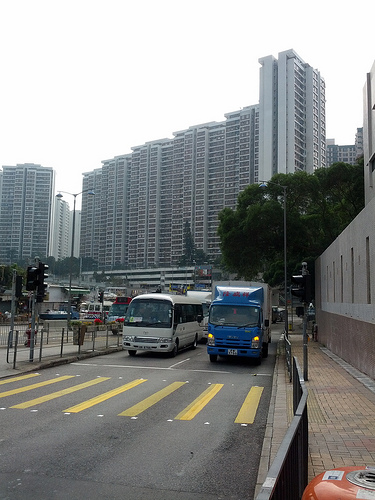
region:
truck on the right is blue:
[202, 274, 277, 365]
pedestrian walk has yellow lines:
[0, 367, 267, 433]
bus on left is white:
[118, 287, 204, 363]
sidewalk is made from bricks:
[263, 330, 373, 498]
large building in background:
[69, 52, 361, 294]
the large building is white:
[75, 45, 360, 287]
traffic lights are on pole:
[20, 256, 46, 302]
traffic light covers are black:
[10, 255, 49, 300]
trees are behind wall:
[207, 154, 372, 296]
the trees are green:
[210, 161, 369, 298]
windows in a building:
[194, 145, 208, 168]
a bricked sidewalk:
[324, 375, 350, 429]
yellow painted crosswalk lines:
[151, 369, 226, 424]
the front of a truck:
[210, 288, 263, 364]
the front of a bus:
[125, 299, 174, 354]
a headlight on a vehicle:
[157, 333, 172, 343]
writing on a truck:
[219, 285, 254, 303]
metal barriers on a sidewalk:
[285, 348, 309, 464]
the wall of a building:
[334, 305, 367, 343]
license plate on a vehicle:
[225, 347, 238, 356]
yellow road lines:
[6, 368, 271, 443]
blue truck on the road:
[204, 275, 282, 366]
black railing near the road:
[278, 335, 326, 498]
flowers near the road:
[61, 310, 129, 330]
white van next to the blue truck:
[116, 283, 208, 367]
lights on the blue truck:
[205, 328, 263, 356]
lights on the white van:
[117, 334, 179, 353]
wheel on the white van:
[161, 337, 181, 356]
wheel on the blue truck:
[204, 341, 219, 365]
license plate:
[225, 342, 238, 357]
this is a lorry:
[208, 280, 264, 356]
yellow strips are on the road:
[5, 370, 256, 419]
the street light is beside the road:
[21, 258, 40, 363]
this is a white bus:
[122, 292, 199, 345]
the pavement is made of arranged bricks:
[311, 376, 358, 452]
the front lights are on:
[207, 334, 268, 342]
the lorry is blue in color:
[207, 288, 264, 354]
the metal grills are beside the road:
[8, 325, 112, 348]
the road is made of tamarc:
[31, 422, 205, 497]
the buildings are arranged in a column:
[83, 58, 306, 176]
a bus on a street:
[104, 289, 209, 366]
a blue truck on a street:
[201, 283, 273, 368]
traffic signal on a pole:
[20, 257, 52, 314]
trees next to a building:
[214, 153, 373, 292]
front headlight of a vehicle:
[156, 333, 175, 349]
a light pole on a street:
[51, 183, 98, 335]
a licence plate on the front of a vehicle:
[223, 346, 241, 361]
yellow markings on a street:
[1, 365, 278, 443]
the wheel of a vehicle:
[189, 330, 201, 351]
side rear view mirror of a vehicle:
[257, 315, 272, 335]